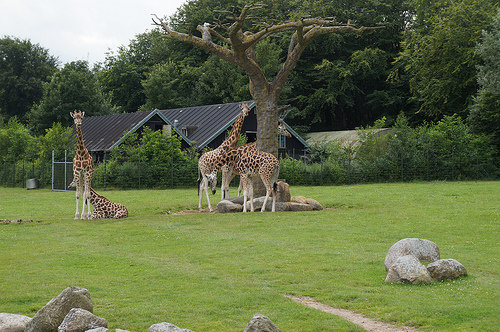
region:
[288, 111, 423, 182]
An arched building beyond the trees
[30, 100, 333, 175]
A house with a black roof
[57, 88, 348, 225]
A house with blue trim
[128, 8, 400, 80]
A tree without any leaves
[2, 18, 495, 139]
Lots of trees with many leaves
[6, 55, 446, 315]
Five giraffes in the grass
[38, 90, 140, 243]
One giraffe standing and one giraffe sitting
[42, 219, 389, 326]
Tracks in the grass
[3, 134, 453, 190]
Fencing in front of the bushes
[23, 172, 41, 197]
A metal barrel near the fence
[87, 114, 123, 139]
the roof top is gray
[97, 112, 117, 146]
the roof is sloped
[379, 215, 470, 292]
the rocks are bolders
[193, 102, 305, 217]
the giraffes are hanging around the tree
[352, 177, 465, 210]
the grass is short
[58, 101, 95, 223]
the giraffe is standing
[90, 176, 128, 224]
the giraffe is laying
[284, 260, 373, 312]
the track is in the grass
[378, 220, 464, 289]
the rocks are white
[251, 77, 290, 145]
the tree trunk is brown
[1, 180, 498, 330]
The grass is green.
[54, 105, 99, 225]
The giraffe is standing.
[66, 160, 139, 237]
Giraffe is lying down.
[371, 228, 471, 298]
Large rocks in grass.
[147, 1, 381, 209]
The tree is bare.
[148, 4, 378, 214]
The tree is tall.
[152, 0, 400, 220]
The tree is leafless.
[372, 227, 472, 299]
The rocks are gray.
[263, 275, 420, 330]
Small ridge is grass.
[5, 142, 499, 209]
A fence in the background.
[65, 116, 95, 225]
a tall giraffe standing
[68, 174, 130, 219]
a small giraffe sitting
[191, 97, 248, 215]
a tall giraffe standing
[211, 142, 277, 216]
a giraffe grazing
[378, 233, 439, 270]
a large grey boulder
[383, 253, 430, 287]
a large grey boulder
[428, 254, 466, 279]
a large grey boulder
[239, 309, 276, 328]
a large grey boulder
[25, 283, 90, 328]
a large grey boulder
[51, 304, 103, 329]
a large grey boulder in foreground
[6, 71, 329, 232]
Five giraffes near a tree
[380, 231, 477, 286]
Three rocks in a group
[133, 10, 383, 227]
Three giraffes by a tree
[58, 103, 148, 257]
Two giraffes next to each other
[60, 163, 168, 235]
A giraffe sitting on the ground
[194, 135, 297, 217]
A giraffe with its neck bent down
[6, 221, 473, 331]
Rocks in the foreground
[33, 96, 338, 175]
A building behind the giraffes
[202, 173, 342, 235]
Rocks at the base of the tree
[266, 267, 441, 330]
Dirt showing through the grass